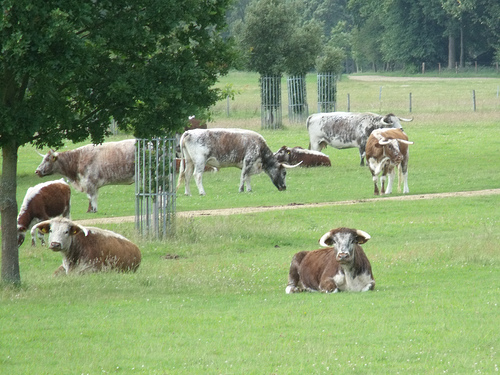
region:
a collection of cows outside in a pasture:
[13, 78, 420, 305]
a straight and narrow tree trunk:
[0, 136, 27, 293]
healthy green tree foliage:
[1, 1, 246, 141]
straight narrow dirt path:
[199, 188, 393, 223]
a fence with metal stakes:
[340, 88, 498, 112]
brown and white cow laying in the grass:
[283, 225, 383, 302]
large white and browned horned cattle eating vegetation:
[174, 127, 302, 200]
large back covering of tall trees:
[341, 3, 498, 78]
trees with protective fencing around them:
[243, 5, 313, 130]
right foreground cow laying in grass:
[276, 220, 383, 312]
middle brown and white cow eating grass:
[172, 122, 304, 198]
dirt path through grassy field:
[13, 176, 497, 237]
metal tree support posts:
[130, 132, 185, 245]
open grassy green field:
[2, 60, 497, 373]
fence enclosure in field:
[205, 88, 499, 119]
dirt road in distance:
[343, 69, 498, 92]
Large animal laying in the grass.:
[299, 225, 381, 311]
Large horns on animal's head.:
[311, 228, 383, 259]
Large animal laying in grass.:
[38, 216, 156, 286]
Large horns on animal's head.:
[28, 216, 100, 254]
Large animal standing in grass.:
[363, 113, 425, 183]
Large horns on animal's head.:
[371, 133, 423, 149]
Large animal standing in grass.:
[191, 122, 288, 189]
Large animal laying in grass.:
[274, 138, 350, 185]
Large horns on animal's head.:
[280, 157, 305, 172]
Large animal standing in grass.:
[308, 105, 421, 133]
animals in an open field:
[12, 10, 470, 355]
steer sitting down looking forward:
[272, 220, 387, 297]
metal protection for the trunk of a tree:
[130, 132, 181, 244]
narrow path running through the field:
[277, 191, 442, 211]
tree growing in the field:
[0, 5, 51, 301]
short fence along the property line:
[405, 85, 495, 111]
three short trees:
[235, 0, 340, 120]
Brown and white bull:
[282, 225, 382, 296]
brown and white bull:
[25, 214, 147, 278]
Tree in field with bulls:
[1, 0, 229, 293]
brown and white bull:
[178, 121, 304, 199]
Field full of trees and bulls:
[0, 5, 497, 307]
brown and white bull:
[360, 123, 415, 199]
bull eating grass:
[175, 118, 303, 198]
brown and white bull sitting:
[283, 221, 385, 296]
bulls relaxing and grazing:
[16, 106, 437, 293]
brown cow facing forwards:
[288, 226, 375, 292]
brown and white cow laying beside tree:
[29, 216, 144, 275]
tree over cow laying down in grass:
[0, 0, 238, 289]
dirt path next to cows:
[68, 188, 499, 227]